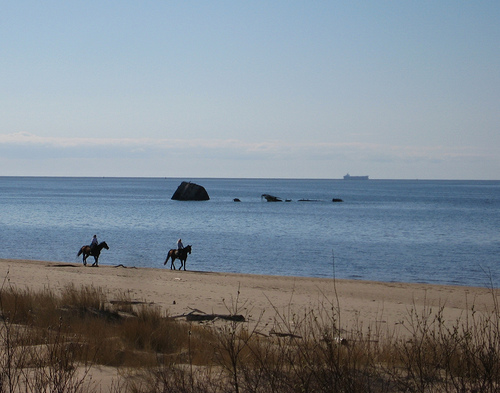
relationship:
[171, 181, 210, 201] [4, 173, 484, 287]
rock in water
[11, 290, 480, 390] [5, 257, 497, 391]
grass on beach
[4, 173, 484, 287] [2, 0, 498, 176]
water under sky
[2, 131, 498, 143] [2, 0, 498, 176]
line in sky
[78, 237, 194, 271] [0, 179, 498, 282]
horsemen in front ocean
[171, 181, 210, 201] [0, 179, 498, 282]
rock in middle of ocean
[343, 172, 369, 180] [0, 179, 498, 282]
ship in ocean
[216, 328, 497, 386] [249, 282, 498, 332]
plants grow in sand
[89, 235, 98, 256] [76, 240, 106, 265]
horsemen on horses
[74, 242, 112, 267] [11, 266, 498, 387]
horses on beach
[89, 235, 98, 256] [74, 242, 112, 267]
horsemen riding horses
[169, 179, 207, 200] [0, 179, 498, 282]
rock out in ocean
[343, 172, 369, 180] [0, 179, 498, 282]
ship out at ocean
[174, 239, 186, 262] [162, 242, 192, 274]
person on horse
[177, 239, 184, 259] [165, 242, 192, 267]
person on horse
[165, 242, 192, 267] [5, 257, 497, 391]
horse on beach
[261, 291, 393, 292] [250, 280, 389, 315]
sand on beach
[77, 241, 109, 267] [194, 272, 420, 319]
horses on sand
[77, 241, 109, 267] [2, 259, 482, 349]
horses walking beach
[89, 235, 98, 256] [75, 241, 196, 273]
horsemen on horses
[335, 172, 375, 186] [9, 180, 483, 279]
ship on water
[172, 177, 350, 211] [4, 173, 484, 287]
items sticking water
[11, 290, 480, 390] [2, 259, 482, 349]
grass on beach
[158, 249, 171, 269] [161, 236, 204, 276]
tail on horse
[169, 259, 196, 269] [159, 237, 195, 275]
legs on horse